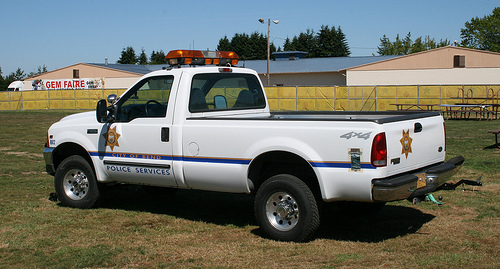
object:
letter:
[53, 80, 63, 90]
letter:
[39, 78, 91, 90]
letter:
[103, 164, 111, 172]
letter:
[132, 165, 140, 175]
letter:
[154, 169, 163, 175]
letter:
[114, 165, 121, 172]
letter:
[45, 81, 51, 89]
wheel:
[52, 153, 104, 208]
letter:
[105, 165, 172, 176]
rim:
[61, 167, 88, 200]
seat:
[230, 89, 258, 108]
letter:
[164, 167, 171, 177]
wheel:
[252, 172, 322, 241]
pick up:
[42, 47, 464, 240]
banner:
[42, 78, 93, 90]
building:
[10, 45, 498, 92]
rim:
[261, 191, 301, 231]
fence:
[3, 82, 498, 111]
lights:
[163, 48, 239, 68]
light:
[370, 129, 391, 168]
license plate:
[412, 171, 429, 189]